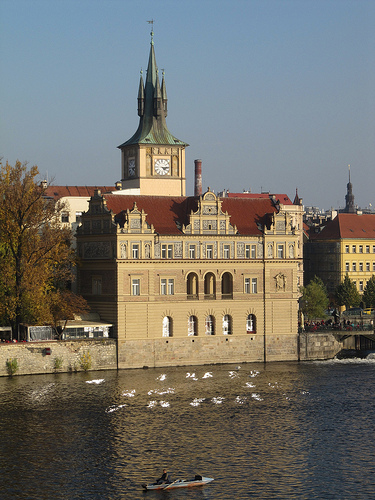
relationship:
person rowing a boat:
[156, 465, 171, 478] [131, 454, 233, 495]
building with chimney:
[79, 184, 309, 337] [191, 154, 204, 198]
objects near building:
[76, 371, 310, 443] [82, 15, 305, 368]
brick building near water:
[76, 186, 303, 371] [0, 357, 373, 498]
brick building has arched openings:
[76, 186, 303, 371] [184, 269, 237, 302]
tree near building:
[0, 154, 72, 344] [70, 182, 307, 369]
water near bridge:
[289, 357, 361, 421] [300, 290, 368, 363]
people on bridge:
[300, 307, 373, 340] [302, 330, 374, 360]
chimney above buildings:
[191, 154, 204, 198] [77, 181, 319, 380]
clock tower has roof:
[117, 16, 190, 197] [117, 27, 192, 147]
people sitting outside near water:
[300, 307, 373, 340] [303, 357, 373, 458]